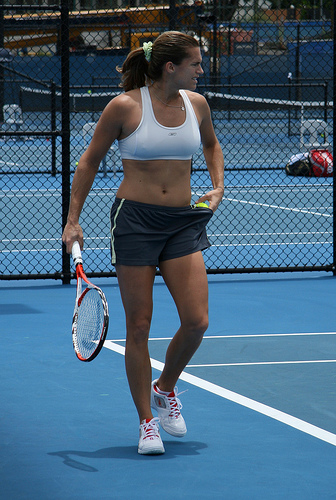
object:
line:
[111, 197, 125, 264]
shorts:
[110, 197, 211, 266]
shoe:
[149, 376, 188, 437]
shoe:
[138, 415, 166, 454]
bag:
[309, 149, 333, 177]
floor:
[0, 102, 332, 499]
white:
[174, 421, 182, 431]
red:
[154, 385, 181, 418]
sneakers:
[137, 418, 165, 455]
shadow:
[47, 441, 208, 472]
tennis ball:
[192, 202, 209, 208]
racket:
[71, 239, 110, 362]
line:
[92, 331, 336, 499]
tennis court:
[2, 56, 335, 498]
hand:
[62, 218, 83, 254]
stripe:
[111, 197, 126, 264]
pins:
[111, 217, 157, 420]